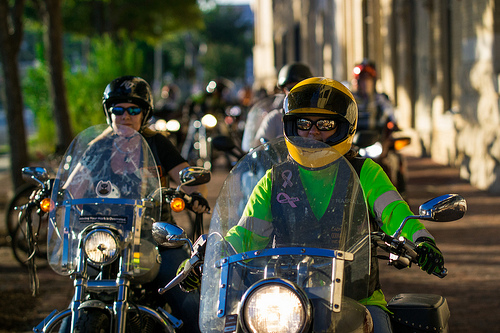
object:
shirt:
[221, 157, 435, 314]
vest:
[271, 157, 381, 302]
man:
[152, 77, 467, 332]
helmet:
[282, 77, 358, 169]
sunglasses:
[297, 118, 338, 131]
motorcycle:
[14, 123, 212, 333]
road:
[1, 155, 498, 333]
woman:
[30, 76, 208, 325]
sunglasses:
[112, 106, 141, 116]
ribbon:
[282, 170, 294, 188]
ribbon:
[277, 193, 299, 208]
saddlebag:
[388, 294, 452, 333]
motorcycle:
[152, 137, 467, 333]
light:
[170, 198, 185, 213]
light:
[40, 198, 55, 212]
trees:
[1, 1, 256, 155]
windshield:
[199, 136, 370, 332]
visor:
[283, 76, 359, 127]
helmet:
[101, 76, 152, 125]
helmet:
[277, 64, 312, 90]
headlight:
[237, 278, 312, 333]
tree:
[0, 0, 255, 159]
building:
[254, 2, 499, 195]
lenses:
[108, 106, 146, 116]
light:
[82, 229, 121, 267]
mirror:
[418, 193, 466, 222]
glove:
[413, 241, 448, 279]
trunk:
[1, 3, 32, 190]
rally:
[12, 61, 466, 333]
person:
[179, 79, 240, 165]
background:
[0, 0, 499, 184]